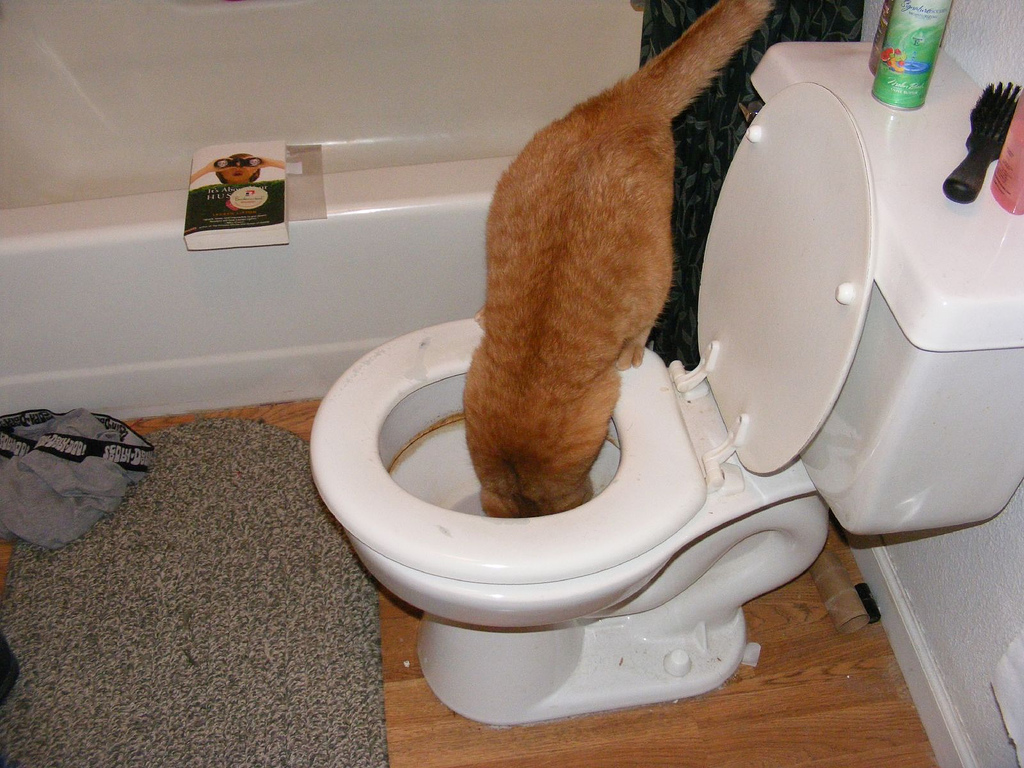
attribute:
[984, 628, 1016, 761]
paper — toilet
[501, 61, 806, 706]
toilet — white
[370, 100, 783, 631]
cat — orange